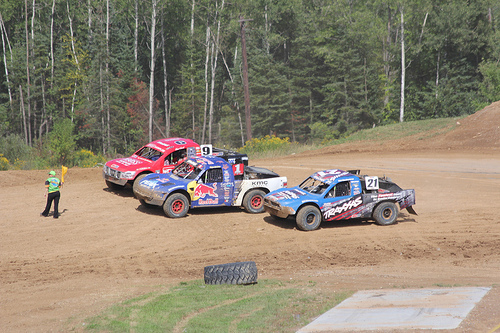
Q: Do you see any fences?
A: No, there are no fences.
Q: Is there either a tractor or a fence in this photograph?
A: No, there are no fences or tractors.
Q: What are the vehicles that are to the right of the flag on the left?
A: The vehicles are cars.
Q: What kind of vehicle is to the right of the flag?
A: The vehicles are cars.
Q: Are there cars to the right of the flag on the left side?
A: Yes, there are cars to the right of the flag.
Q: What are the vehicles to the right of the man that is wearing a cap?
A: The vehicles are cars.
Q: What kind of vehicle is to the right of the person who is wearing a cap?
A: The vehicles are cars.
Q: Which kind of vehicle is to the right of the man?
A: The vehicles are cars.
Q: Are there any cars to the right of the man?
A: Yes, there are cars to the right of the man.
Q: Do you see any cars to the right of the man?
A: Yes, there are cars to the right of the man.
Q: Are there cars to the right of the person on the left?
A: Yes, there are cars to the right of the man.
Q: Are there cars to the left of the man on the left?
A: No, the cars are to the right of the man.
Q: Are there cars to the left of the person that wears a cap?
A: No, the cars are to the right of the man.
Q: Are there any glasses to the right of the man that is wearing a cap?
A: No, there are cars to the right of the man.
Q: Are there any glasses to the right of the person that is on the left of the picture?
A: No, there are cars to the right of the man.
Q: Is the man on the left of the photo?
A: Yes, the man is on the left of the image.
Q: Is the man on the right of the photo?
A: No, the man is on the left of the image.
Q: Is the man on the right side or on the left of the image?
A: The man is on the left of the image.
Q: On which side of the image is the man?
A: The man is on the left of the image.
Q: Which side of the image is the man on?
A: The man is on the left of the image.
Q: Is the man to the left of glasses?
A: No, the man is to the left of the cars.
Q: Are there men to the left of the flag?
A: Yes, there is a man to the left of the flag.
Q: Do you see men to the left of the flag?
A: Yes, there is a man to the left of the flag.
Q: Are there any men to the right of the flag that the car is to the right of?
A: No, the man is to the left of the flag.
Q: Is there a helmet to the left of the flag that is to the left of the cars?
A: No, there is a man to the left of the flag.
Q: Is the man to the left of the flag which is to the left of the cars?
A: Yes, the man is to the left of the flag.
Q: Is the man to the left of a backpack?
A: No, the man is to the left of the flag.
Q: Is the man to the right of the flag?
A: No, the man is to the left of the flag.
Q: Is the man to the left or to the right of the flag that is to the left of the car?
A: The man is to the left of the flag.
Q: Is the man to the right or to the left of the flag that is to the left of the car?
A: The man is to the left of the flag.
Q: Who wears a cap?
A: The man wears a cap.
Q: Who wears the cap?
A: The man wears a cap.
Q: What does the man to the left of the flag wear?
A: The man wears a cap.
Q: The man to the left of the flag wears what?
A: The man wears a cap.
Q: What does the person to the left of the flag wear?
A: The man wears a cap.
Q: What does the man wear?
A: The man wears a cap.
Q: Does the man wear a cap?
A: Yes, the man wears a cap.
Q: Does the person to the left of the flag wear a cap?
A: Yes, the man wears a cap.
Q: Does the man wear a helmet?
A: No, the man wears a cap.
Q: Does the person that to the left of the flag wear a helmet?
A: No, the man wears a cap.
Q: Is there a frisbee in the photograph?
A: No, there are no frisbees.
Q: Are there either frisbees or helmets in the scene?
A: No, there are no frisbees or helmets.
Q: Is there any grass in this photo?
A: Yes, there is grass.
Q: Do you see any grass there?
A: Yes, there is grass.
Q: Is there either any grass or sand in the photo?
A: Yes, there is grass.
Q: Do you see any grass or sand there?
A: Yes, there is grass.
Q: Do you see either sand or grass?
A: Yes, there is grass.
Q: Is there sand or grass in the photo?
A: Yes, there is grass.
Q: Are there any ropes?
A: No, there are no ropes.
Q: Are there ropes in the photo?
A: No, there are no ropes.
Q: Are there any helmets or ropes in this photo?
A: No, there are no ropes or helmets.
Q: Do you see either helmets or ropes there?
A: No, there are no ropes or helmets.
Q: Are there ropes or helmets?
A: No, there are no ropes or helmets.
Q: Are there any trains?
A: No, there are no trains.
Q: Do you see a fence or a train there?
A: No, there are no trains or fences.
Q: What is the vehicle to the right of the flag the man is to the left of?
A: The vehicle is a car.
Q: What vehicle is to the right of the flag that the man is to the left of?
A: The vehicle is a car.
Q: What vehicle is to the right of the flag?
A: The vehicle is a car.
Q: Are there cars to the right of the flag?
A: Yes, there is a car to the right of the flag.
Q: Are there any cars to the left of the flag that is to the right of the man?
A: No, the car is to the right of the flag.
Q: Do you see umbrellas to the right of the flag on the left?
A: No, there is a car to the right of the flag.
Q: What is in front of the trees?
A: The car is in front of the trees.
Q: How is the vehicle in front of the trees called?
A: The vehicle is a car.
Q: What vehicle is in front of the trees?
A: The vehicle is a car.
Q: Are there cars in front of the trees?
A: Yes, there is a car in front of the trees.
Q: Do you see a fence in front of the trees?
A: No, there is a car in front of the trees.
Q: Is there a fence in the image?
A: No, there are no fences.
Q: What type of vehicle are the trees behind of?
A: The trees are behind the car.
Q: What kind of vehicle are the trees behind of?
A: The trees are behind the car.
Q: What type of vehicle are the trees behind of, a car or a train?
A: The trees are behind a car.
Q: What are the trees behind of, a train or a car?
A: The trees are behind a car.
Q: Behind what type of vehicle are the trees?
A: The trees are behind the car.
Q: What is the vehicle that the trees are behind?
A: The vehicle is a car.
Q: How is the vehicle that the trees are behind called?
A: The vehicle is a car.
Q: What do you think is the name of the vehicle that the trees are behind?
A: The vehicle is a car.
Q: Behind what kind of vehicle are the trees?
A: The trees are behind the car.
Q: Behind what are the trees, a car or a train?
A: The trees are behind a car.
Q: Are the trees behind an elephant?
A: No, the trees are behind the car.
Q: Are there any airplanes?
A: No, there are no airplanes.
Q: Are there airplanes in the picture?
A: No, there are no airplanes.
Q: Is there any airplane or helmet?
A: No, there are no airplanes or helmets.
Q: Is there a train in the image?
A: No, there are no trains.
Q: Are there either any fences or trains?
A: No, there are no trains or fences.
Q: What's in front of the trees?
A: The car is in front of the trees.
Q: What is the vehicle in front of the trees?
A: The vehicle is a car.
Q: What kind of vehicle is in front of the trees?
A: The vehicle is a car.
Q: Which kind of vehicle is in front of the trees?
A: The vehicle is a car.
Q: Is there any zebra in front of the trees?
A: No, there is a car in front of the trees.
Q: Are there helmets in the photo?
A: No, there are no helmets.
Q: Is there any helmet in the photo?
A: No, there are no helmets.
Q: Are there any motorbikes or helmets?
A: No, there are no helmets or motorbikes.